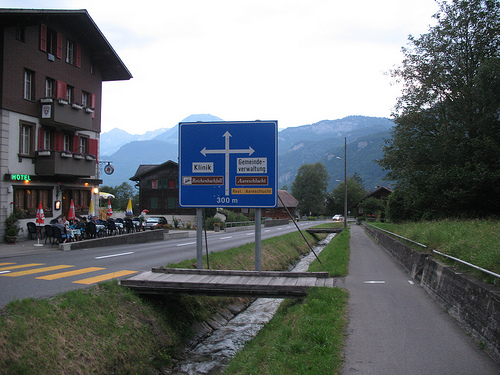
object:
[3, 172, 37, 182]
sign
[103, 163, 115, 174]
sign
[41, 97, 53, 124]
sign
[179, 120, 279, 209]
sign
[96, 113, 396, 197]
mountain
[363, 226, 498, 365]
wall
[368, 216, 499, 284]
grass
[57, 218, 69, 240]
people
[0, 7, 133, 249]
restaurant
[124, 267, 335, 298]
bridge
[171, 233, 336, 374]
waters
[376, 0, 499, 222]
tree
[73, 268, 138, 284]
markings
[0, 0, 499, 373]
background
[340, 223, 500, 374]
side road